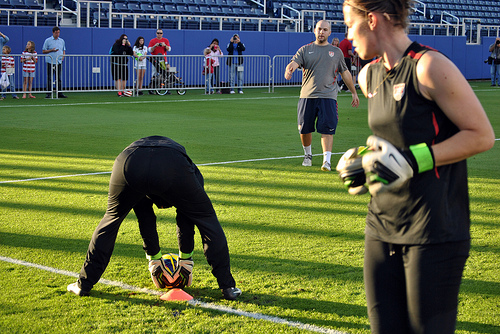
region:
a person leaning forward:
[62, 84, 240, 325]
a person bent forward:
[19, 101, 271, 324]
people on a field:
[100, 2, 465, 315]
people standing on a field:
[124, 40, 494, 330]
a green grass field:
[21, 126, 404, 332]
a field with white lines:
[26, 77, 480, 329]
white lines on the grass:
[41, 126, 311, 320]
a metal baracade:
[65, 34, 387, 114]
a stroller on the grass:
[107, 36, 251, 116]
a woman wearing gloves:
[319, 12, 473, 280]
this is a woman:
[353, 79, 442, 284]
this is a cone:
[153, 284, 193, 306]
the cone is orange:
[126, 275, 210, 329]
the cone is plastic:
[98, 272, 223, 330]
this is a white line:
[246, 297, 266, 314]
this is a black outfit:
[150, 169, 186, 226]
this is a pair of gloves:
[296, 122, 357, 255]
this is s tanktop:
[266, 37, 446, 187]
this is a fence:
[108, 56, 138, 72]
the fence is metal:
[83, 66, 135, 123]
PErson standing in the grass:
[1, 40, 31, 103]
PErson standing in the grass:
[18, 33, 38, 119]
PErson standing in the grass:
[35, 21, 70, 81]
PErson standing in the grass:
[104, 23, 135, 83]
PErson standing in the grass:
[135, 29, 149, 89]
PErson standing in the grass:
[148, 25, 172, 84]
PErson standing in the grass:
[176, 23, 226, 96]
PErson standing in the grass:
[223, 31, 248, 89]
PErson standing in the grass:
[290, 15, 332, 165]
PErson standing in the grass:
[339, 4, 449, 329]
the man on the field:
[62, 113, 268, 299]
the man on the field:
[317, 2, 492, 327]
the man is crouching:
[10, 100, 266, 320]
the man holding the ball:
[76, 127, 284, 307]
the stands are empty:
[107, 1, 278, 24]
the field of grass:
[18, 96, 498, 296]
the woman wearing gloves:
[327, 12, 481, 332]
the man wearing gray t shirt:
[280, 36, 357, 112]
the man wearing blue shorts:
[292, 95, 352, 140]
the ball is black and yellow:
[157, 247, 202, 291]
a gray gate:
[55, 52, 130, 90]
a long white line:
[195, 147, 300, 167]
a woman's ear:
[361, 10, 376, 32]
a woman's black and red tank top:
[350, 41, 477, 246]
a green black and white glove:
[350, 131, 435, 195]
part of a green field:
[0, 88, 377, 332]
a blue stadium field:
[163, 3, 175, 15]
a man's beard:
[316, 34, 328, 41]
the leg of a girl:
[27, 72, 35, 97]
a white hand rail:
[430, 10, 460, 33]